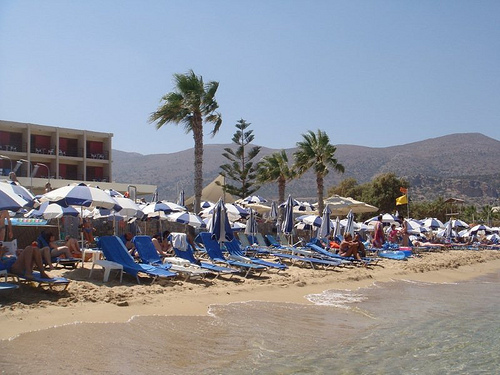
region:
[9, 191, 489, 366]
water and sand in beach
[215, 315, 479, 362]
water near the sand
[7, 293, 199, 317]
sand region of beach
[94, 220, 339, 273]
beach chairs that are empty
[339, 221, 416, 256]
people on the beach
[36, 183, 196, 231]
tent umbrellas on the sand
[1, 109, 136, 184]
building on the sand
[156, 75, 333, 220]
trees on the sand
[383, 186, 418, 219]
flags on the beach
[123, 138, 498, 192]
land in the distance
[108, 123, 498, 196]
mountains are brown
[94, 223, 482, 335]
blue chairs in front the beach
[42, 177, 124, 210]
a white and blue parasol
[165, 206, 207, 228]
a white and blue parasol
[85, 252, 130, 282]
a table next a blue chair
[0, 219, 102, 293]
people on the beach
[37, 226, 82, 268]
person lying on a blue chair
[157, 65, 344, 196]
palms behind the parasols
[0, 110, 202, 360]
a building in front the beach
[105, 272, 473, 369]
sea water on the sand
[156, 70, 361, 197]
four tropical trees swaying in the wind at the beach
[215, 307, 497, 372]
clear calm and shallow waters at the beach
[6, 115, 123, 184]
section of a resort hotel near the beach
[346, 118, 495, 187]
large mountain in the distance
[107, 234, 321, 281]
many beach chairs covered in blue towels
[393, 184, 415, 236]
a red and yellow flag at the beach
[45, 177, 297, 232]
several blue and white striped umbrellas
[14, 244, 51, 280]
legs of a person laying in a beach chair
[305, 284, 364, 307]
white foam of the water lapping on the sand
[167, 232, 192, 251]
a white towel on the beach chair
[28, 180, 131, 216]
umbrella on a beach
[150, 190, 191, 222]
umbrella on a beach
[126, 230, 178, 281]
chair on a beach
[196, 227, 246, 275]
chair on a beach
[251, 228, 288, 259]
chair on a beach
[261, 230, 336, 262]
chair on a beach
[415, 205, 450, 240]
umbrella on a beach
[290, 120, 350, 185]
tree on a beach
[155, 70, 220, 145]
tree on a beach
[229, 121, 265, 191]
trees on a beach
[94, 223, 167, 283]
blue beach chairs in sand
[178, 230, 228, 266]
blue beach chairs in sand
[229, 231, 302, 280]
blue beach chairs in sand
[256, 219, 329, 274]
blue beach chairs in sand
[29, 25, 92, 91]
white clouds in blue sky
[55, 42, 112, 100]
white clouds in blue sky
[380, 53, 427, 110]
white clouds in blue sky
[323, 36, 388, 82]
white clouds in blue sky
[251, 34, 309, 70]
white clouds in blue sky